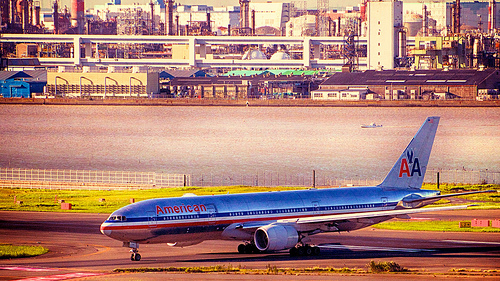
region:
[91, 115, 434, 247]
an airplane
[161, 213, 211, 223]
windows on the airplane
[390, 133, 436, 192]
the tail of the airplane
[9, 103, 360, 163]
the water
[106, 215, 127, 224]
the windshield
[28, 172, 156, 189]
the fence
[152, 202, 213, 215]
American sign on plane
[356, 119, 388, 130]
boat in the water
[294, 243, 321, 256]
wheels on the airplane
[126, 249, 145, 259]
the front wheels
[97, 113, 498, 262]
a large airplane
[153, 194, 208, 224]
the word american in red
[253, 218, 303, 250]
a large plane engine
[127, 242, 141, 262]
the front wheel of an plane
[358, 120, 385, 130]
a small motor boat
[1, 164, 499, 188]
a long white fence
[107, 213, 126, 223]
windsheild of a plane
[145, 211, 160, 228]
an airplane door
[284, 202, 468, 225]
the left plan wing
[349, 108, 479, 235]
the back of a plane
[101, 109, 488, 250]
An American Airlines plane on the runway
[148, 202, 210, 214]
The American Airlines logo on the plane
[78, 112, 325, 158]
Water behind the plane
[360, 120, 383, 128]
A boat on the water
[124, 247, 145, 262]
The front wheel of the plane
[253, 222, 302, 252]
The left engine on the plane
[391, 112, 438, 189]
The tail of the airplane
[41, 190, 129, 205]
Green grass by the airplane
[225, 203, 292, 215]
Windows on the airplane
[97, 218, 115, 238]
The nose of the airplane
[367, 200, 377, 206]
part of a plate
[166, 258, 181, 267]
part of a run way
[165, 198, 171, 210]
top of a plane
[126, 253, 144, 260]
wheel of a plane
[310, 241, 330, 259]
edge of a wheel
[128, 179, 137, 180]
part of a fence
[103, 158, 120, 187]
edge of a fence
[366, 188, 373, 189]
back of a plane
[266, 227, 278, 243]
part of an engine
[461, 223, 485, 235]
part of a field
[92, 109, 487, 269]
airplane on the runway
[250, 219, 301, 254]
engine of an airplane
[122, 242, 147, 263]
front landing gear of an airplane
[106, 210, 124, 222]
windshield of an airplane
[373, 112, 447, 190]
tail of an airplane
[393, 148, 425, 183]
logo on an airplane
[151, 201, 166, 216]
red letter painted on airplane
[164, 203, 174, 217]
red letter painted on airplane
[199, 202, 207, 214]
red letter painted on airplane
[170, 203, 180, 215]
red letter painted on airplane